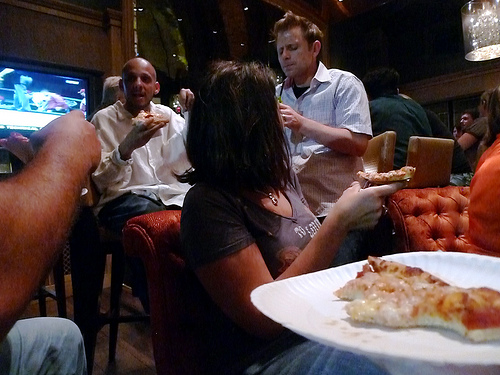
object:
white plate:
[249, 250, 499, 368]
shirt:
[90, 99, 195, 207]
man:
[89, 57, 194, 245]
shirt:
[180, 166, 320, 361]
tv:
[0, 57, 104, 155]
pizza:
[355, 164, 418, 185]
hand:
[332, 179, 407, 231]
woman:
[169, 57, 410, 373]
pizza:
[131, 106, 176, 128]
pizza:
[0, 133, 92, 206]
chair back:
[390, 185, 472, 251]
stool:
[107, 253, 123, 368]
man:
[271, 10, 377, 268]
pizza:
[335, 254, 499, 342]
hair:
[168, 62, 296, 199]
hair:
[275, 10, 325, 45]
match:
[0, 68, 86, 130]